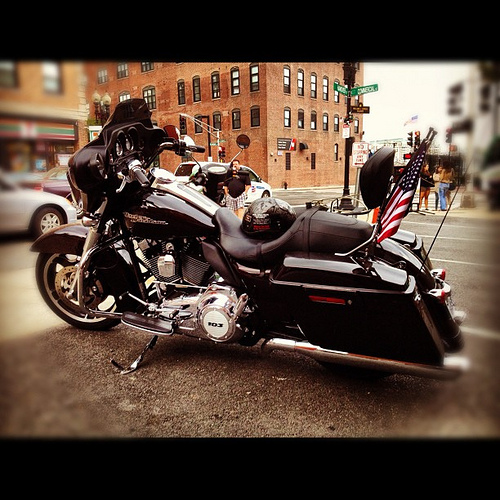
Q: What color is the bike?
A: Black.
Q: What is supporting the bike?
A: Kickstand.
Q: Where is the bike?
A: Parking space.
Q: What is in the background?
A: Building.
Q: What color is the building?
A: Brown.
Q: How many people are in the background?
A: Five.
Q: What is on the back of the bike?
A: Flag.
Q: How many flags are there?
A: One.